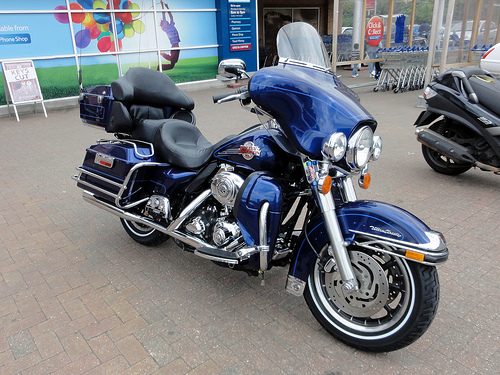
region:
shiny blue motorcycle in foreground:
[76, 27, 460, 339]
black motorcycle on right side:
[401, 47, 499, 174]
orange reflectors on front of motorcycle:
[321, 172, 431, 259]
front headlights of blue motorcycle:
[333, 125, 382, 172]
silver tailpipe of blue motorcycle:
[77, 173, 210, 255]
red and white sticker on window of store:
[362, 15, 390, 50]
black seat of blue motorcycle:
[111, 73, 211, 170]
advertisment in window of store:
[7, 3, 219, 95]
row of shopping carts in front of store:
[368, 36, 465, 92]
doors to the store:
[260, 8, 328, 63]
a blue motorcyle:
[76, 60, 440, 352]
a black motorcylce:
[408, 58, 498, 173]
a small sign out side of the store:
[0, 44, 55, 122]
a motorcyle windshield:
[270, 26, 342, 93]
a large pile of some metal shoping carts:
[375, 39, 432, 92]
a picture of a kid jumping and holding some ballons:
[145, 5, 187, 75]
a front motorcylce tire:
[288, 210, 449, 356]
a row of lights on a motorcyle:
[321, 111, 378, 166]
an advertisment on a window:
[360, 13, 391, 49]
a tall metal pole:
[430, 0, 443, 110]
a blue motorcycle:
[61, 17, 458, 363]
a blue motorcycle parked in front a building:
[6, 0, 455, 357]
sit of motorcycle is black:
[66, 25, 452, 352]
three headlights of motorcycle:
[306, 115, 392, 177]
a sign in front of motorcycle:
[0, 51, 57, 126]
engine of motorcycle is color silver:
[153, 160, 275, 269]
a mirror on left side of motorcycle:
[205, 48, 272, 96]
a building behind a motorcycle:
[3, 4, 457, 356]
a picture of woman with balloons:
[46, 3, 208, 79]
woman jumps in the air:
[144, 3, 199, 78]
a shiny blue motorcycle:
[72, 20, 449, 355]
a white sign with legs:
[0, 58, 47, 118]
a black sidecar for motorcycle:
[417, 41, 499, 178]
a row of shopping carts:
[370, 45, 431, 93]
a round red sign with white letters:
[362, 13, 384, 48]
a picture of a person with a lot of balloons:
[52, 3, 183, 71]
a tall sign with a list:
[225, 1, 251, 51]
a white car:
[438, 19, 498, 49]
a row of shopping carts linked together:
[320, 33, 355, 63]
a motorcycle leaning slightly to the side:
[77, 20, 447, 355]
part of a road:
[117, 335, 133, 358]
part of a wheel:
[377, 298, 406, 332]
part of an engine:
[217, 240, 257, 259]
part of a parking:
[32, 273, 67, 312]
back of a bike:
[131, 223, 143, 238]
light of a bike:
[321, 129, 360, 181]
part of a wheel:
[354, 307, 379, 342]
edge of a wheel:
[371, 249, 385, 258]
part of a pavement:
[75, 151, 78, 167]